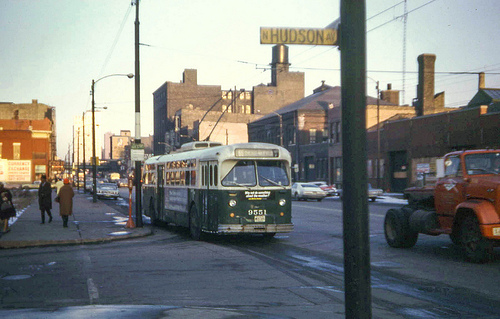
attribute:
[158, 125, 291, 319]
vehicle — old style and red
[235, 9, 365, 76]
sign — retangular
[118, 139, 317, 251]
bus — green, silver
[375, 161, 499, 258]
vehicle — red, old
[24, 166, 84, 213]
people — walking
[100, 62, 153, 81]
post — tall, wooden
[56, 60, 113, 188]
light — metal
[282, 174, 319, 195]
vehicle — white, old, sedan, driving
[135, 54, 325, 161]
building — brown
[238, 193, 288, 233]
number — white, reading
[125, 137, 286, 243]
bus — old, white, green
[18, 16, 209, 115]
sky — white, cloudy, blue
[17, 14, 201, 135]
sky — white, cloudy, blue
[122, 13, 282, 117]
sky — blue, white, cloudy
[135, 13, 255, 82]
sky — cloudy, white, blue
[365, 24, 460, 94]
sky — blue, white, cloudy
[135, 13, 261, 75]
sky — cloudy, white, blue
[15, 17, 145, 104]
sky — blue, white, cloudy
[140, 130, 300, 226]
bus — green, white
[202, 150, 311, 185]
bus — white, green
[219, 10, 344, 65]
sign — yellow, black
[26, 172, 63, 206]
person — walking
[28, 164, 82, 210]
person — walking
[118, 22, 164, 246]
pole — black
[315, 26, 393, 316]
pole — black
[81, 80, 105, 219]
pole — black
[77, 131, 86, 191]
pole — black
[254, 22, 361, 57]
sign — vintage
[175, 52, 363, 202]
buildings — brick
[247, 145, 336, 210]
cars — vintage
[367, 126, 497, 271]
truck — red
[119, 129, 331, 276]
bus — green, silver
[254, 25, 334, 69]
sign — rectangular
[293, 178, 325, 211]
vehicle — old, white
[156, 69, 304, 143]
building — brown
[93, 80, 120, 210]
post — large, wooden